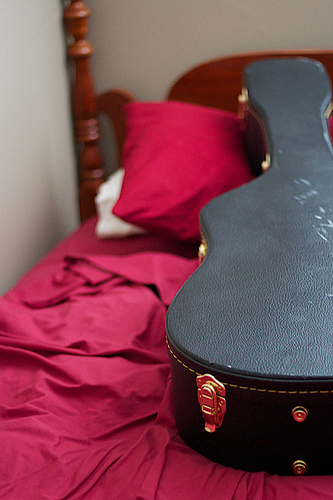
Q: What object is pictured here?
A: Guitar.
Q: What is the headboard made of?
A: Wood.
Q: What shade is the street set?
A: Red.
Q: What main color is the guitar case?
A: Black.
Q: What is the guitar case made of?
A: Leather.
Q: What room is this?
A: Bedroom.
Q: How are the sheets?
A: Ruffled.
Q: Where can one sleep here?
A: On the bed.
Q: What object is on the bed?
A: Instrument case.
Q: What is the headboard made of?
A: Wood.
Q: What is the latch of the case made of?
A: Metal.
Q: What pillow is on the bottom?
A: The white one.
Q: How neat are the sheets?
A: Wrinkled.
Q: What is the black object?
A: Guitar case.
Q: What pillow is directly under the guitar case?
A: The red one.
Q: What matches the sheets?
A: The red pillow.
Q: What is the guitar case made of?
A: Leather.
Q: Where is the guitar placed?
A: On bed.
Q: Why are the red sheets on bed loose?
A: Unmade.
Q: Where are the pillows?
A: Beside guitar.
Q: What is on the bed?
A: Guitar.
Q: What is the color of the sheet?
A: Pink.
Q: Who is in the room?
A: No one.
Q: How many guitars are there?
A: 1.